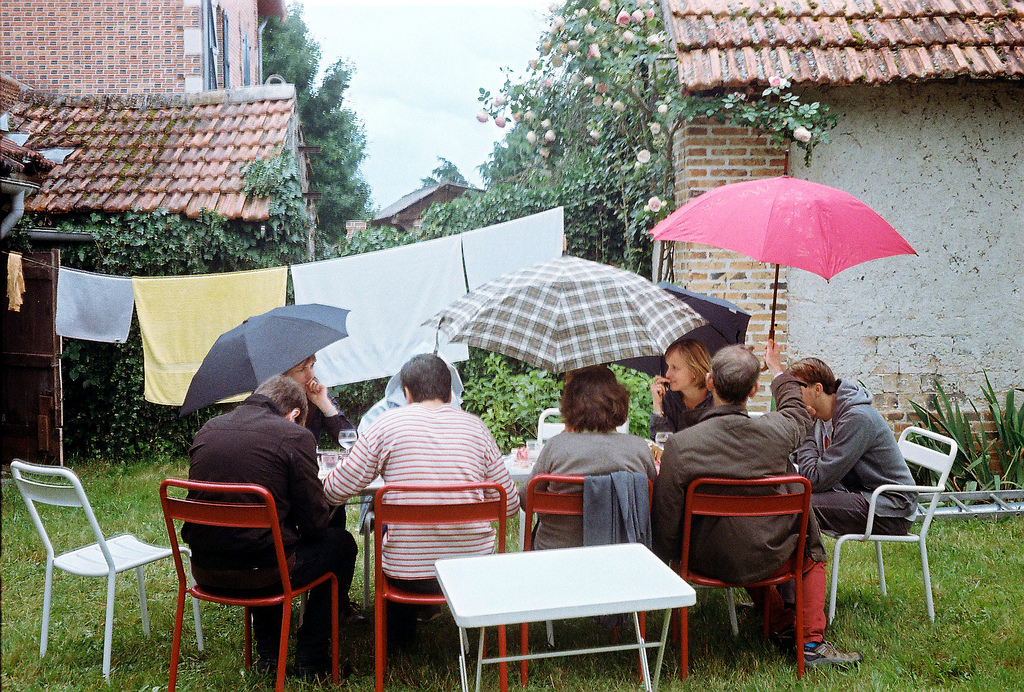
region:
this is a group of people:
[52, 86, 985, 650]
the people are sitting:
[152, 233, 909, 505]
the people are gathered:
[295, 171, 786, 615]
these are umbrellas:
[196, 130, 851, 419]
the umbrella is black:
[122, 206, 414, 416]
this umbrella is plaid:
[456, 236, 698, 379]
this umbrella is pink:
[675, 124, 882, 308]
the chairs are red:
[178, 464, 496, 621]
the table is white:
[336, 519, 777, 679]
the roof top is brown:
[105, 66, 280, 226]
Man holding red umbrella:
[657, 175, 902, 657]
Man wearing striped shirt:
[325, 399, 535, 581]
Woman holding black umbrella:
[184, 300, 363, 462]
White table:
[429, 542, 706, 689]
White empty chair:
[9, 452, 213, 668]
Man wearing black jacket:
[182, 373, 361, 675]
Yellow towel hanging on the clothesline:
[135, 267, 291, 404]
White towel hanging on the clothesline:
[288, 229, 472, 376]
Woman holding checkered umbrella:
[439, 253, 697, 558]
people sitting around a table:
[157, 258, 965, 670]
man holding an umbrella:
[647, 170, 922, 687]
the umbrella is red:
[648, 161, 921, 276]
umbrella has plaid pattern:
[422, 252, 710, 379]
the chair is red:
[155, 473, 348, 686]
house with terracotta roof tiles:
[0, 79, 321, 472]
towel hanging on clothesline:
[2, 173, 682, 411]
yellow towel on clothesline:
[136, 262, 301, 408]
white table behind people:
[429, 538, 696, 685]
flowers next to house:
[471, 2, 835, 436]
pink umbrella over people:
[626, 113, 950, 304]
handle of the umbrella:
[732, 269, 824, 337]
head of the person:
[758, 319, 885, 441]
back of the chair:
[141, 456, 310, 641]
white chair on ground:
[24, 430, 179, 665]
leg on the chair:
[82, 535, 152, 688]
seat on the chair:
[66, 499, 185, 601]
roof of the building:
[5, 86, 304, 232]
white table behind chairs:
[425, 527, 685, 635]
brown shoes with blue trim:
[786, 628, 884, 674]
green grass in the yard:
[963, 555, 1012, 653]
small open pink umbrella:
[645, 145, 934, 282]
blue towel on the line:
[31, 240, 142, 352]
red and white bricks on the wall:
[647, 133, 756, 165]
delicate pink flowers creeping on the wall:
[591, 42, 830, 157]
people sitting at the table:
[155, 311, 942, 616]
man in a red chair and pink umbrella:
[644, 171, 911, 680]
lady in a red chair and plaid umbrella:
[441, 256, 702, 548]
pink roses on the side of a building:
[501, 3, 835, 196]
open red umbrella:
[648, 123, 905, 298]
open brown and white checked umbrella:
[431, 256, 722, 392]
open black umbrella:
[174, 285, 380, 419]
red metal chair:
[133, 462, 383, 682]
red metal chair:
[346, 454, 531, 671]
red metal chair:
[655, 439, 829, 678]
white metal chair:
[808, 395, 963, 614]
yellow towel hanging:
[121, 244, 296, 435]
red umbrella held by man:
[647, 165, 924, 286]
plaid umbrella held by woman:
[428, 249, 708, 376]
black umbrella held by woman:
[178, 300, 350, 412]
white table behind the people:
[432, 537, 696, 690]